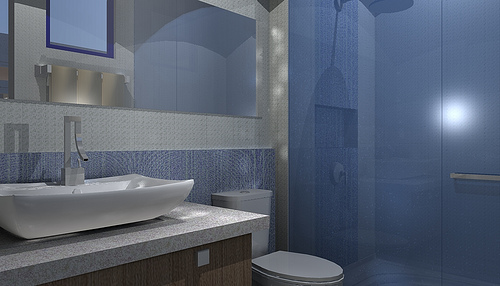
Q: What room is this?
A: Bathroom.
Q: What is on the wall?
A: Mirror.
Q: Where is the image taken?
A: In bathroom.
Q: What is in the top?
A: Sink.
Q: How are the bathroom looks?
A: Blue walls.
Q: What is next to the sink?
A: Toilet.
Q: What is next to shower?
A: Toilet.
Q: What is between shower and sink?
A: Toilet.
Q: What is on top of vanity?
A: Sink.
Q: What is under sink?
A: Corian.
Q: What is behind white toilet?
A: Wall.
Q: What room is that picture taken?
A: The bathroom.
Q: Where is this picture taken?
A: Bathroom.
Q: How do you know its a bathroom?
A: The toilet.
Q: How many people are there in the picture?
A: None.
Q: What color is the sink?
A: White.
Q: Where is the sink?
A: It is next to the toilet.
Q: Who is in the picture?
A: No one.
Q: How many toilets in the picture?
A: One.